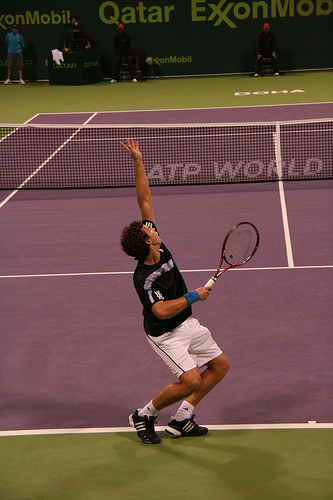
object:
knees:
[181, 357, 230, 390]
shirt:
[4, 30, 24, 53]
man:
[5, 25, 26, 86]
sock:
[174, 399, 195, 421]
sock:
[138, 398, 159, 417]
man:
[109, 23, 137, 84]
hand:
[195, 286, 212, 301]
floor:
[0, 68, 333, 500]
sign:
[234, 88, 304, 95]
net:
[0, 118, 332, 190]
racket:
[203, 221, 259, 287]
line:
[255, 118, 322, 271]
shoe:
[165, 413, 208, 437]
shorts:
[143, 316, 223, 379]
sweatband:
[183, 290, 200, 307]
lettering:
[0, 7, 71, 28]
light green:
[137, 83, 179, 107]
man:
[120, 139, 229, 445]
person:
[252, 22, 281, 79]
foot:
[129, 408, 161, 444]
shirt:
[133, 220, 193, 337]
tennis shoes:
[129, 408, 208, 445]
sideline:
[3, 76, 236, 103]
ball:
[145, 57, 152, 66]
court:
[0, 99, 333, 439]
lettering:
[98, 0, 174, 27]